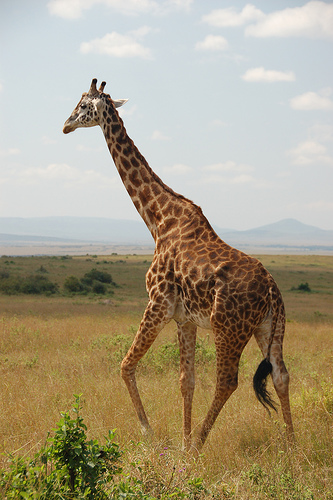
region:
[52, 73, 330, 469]
Giraffe in the wild.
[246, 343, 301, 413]
Black tail on the giraffe.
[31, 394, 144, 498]
Green plant in the grass.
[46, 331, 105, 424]
Yellow, dried out grass.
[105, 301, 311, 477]
Four legs on the giraffe.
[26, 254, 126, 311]
Bushes in the background.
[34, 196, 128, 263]
Mountains behind the field.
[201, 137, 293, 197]
White clouds in the sky.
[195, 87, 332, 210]
Blue sky with white clouds.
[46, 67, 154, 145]
Face on the giraffe.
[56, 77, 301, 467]
Giraffe in the grass.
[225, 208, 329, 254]
Mountains in the background.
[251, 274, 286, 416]
Black hair on tail of giraffe.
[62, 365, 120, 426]
Tall brown grass in the landscape.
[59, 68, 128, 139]
Two horns on giraffe's head.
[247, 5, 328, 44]
White clouds in the sky.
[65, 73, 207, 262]
Brown spots on the giraffe.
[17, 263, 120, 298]
Green bushes in the landscape.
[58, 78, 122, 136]
Black eyes on giraffe.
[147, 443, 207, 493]
Purple wild flowers in the grass.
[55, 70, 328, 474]
giraffe walking in the grass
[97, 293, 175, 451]
front leg is bent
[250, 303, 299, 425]
long tail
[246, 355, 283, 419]
long black hairs at the end of the tail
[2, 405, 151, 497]
small green bush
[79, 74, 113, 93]
two tiny horns sticking out of the top of the head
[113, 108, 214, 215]
hair running along the long neck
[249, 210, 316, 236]
hill in the distance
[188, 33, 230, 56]
small white cloud in the sky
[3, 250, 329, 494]
large field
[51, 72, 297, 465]
a giraffe, walking away, in the savanna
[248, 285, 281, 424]
slightly breezy weather+action of walking make tail swing, flurry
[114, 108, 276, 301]
bumpy neck back hips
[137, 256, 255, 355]
angled shoulder, angled thigh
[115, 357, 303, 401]
knobby giraffe knees, as ever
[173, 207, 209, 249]
wrinkles @ base of neck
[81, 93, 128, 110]
white ears pointed backward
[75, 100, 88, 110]
half-shut eye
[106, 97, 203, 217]
sparshe mane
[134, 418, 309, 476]
hooves hidden amid the dry grass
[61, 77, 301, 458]
a tall giraffe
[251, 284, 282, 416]
the tail of a giraffe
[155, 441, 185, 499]
wildflowers on a savannah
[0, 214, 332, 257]
a range of mountains in the background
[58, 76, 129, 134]
the head of a giraffe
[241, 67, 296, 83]
a cloud in a partly cloudly sky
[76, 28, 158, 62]
a cloud in a partly cloudy sky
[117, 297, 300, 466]
the four legs of a giraffe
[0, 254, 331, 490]
a savannah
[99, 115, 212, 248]
the very long neck of a giraffe